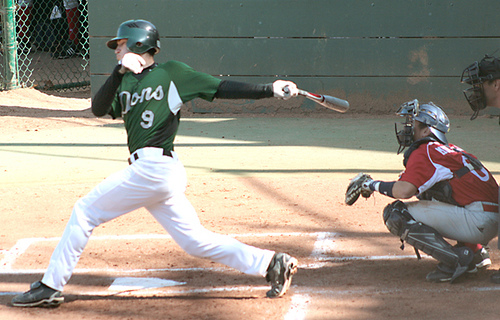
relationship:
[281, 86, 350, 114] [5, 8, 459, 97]
bat in air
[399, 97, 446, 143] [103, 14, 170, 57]
helmet on head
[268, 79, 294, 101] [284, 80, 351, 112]
hand holding bat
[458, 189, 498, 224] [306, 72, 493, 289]
belt on catcher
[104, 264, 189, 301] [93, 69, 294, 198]
base on field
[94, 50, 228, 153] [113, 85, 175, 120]
top with letters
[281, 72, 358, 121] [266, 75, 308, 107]
bat in hand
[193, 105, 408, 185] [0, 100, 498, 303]
shadows on dirt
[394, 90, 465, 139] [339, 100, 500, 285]
hat on catcher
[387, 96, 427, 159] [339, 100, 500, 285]
face mask on catcher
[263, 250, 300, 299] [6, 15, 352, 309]
baseball cleat on baseball player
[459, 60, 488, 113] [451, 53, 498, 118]
face mask on umpire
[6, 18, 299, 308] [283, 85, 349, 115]
baseball player swinging bat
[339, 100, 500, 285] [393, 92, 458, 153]
catcher wearing helmet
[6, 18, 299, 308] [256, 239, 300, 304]
baseball player wearing baseball cleat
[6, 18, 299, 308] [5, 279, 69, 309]
baseball player wearing cleat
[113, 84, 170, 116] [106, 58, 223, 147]
lettering on jersey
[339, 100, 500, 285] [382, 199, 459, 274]
catcher wearing shin guard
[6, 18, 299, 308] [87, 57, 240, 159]
baseball player wearing green shirt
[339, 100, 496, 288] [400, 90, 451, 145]
catcher wearing helmet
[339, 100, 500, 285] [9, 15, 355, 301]
catcher behind batter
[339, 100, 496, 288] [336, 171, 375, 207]
catcher wearing mitt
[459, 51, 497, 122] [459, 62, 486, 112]
umpire wearing face mask